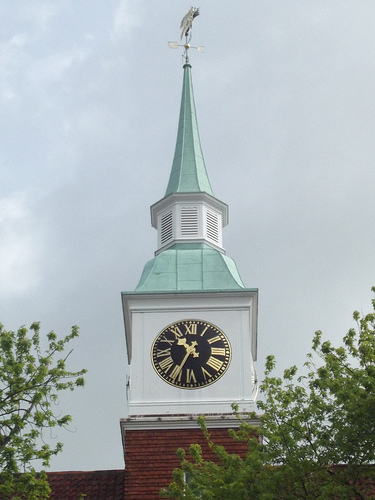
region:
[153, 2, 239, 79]
A weather vane atop a cupola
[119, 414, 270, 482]
Red brick supporting a clock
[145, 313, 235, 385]
A clock tower with a black face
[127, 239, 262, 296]
Green metal roofing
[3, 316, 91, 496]
A tree reaching toward the clock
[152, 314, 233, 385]
Gold roman numerals on the clock face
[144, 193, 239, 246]
Air vents in the cupola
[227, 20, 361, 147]
A soft blue sky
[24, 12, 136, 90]
A few small clouds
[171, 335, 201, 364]
Golden clock hands pointing out the numbers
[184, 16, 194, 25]
top of a building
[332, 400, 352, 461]
branches of a tree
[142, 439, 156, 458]
section of a brick wall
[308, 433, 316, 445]
leaves of a tree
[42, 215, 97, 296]
section of dark clouds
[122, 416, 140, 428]
edge of a building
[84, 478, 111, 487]
roof of a building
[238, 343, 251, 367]
white wall of a building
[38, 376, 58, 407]
branches of a tall tree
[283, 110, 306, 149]
part of a white cloud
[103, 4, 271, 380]
light blue-green roof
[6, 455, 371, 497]
red clay shingles on a roof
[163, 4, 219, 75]
a silver weather cock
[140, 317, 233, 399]
a black clock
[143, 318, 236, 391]
gold tick marks on a clock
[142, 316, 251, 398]
gold tick marks forming a circle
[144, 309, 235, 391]
roman numerals on a clock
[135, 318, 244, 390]
gold roman numerals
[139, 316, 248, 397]
roman numerals in a circle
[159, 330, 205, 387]
two gold hands on a clock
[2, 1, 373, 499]
the building has a clock tower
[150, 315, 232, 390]
the face of the clock is black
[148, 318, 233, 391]
the hands of the clock are gold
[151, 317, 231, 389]
the clock has gold Roman numerals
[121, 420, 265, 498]
the base of the clock is red brick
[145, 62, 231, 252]
the cupola is green with white louvers underneath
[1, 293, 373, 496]
the tower is between green trees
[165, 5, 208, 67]
a directional weather vane is on top of the cupola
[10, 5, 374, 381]
the sky is cloudy and blue gray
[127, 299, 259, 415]
white wood is on the steeple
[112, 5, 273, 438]
the tall steeple and clock on a brick church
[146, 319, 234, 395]
the black and gold clock with roman numerals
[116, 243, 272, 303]
a light green dome shape of the base of the steeple on the church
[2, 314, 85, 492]
green leaved branches from a nearby tree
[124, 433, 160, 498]
the red brick of the church building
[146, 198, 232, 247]
a round white area with ventilation slats in it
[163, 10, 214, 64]
a white metal weather vain at the very top of the steeple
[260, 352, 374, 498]
a large green tree next to the church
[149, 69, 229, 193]
the light green pointed shape of the steeple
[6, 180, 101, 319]
a very cloudy white sky